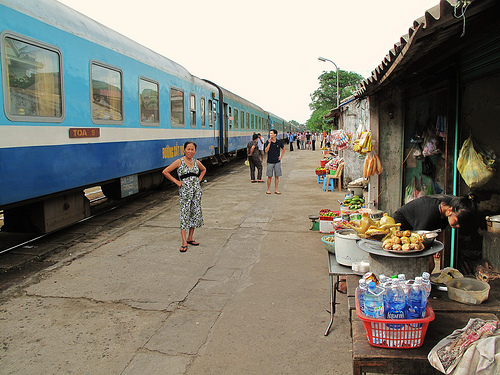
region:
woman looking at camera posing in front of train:
[166, 133, 222, 263]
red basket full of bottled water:
[344, 258, 436, 365]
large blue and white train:
[7, 35, 244, 185]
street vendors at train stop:
[322, 53, 438, 371]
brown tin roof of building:
[345, 0, 490, 112]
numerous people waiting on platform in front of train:
[174, 98, 329, 260]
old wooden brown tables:
[340, 296, 497, 367]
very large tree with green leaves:
[304, 56, 369, 138]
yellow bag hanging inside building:
[445, 118, 499, 194]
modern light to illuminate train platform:
[315, 40, 348, 120]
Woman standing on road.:
[156, 120, 273, 260]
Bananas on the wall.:
[357, 125, 465, 212]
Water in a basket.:
[339, 283, 456, 370]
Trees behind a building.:
[245, 24, 498, 241]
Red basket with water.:
[340, 266, 450, 356]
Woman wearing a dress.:
[147, 142, 239, 314]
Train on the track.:
[104, 17, 402, 276]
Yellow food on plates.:
[342, 196, 449, 293]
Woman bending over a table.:
[397, 167, 497, 253]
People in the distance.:
[232, 97, 330, 204]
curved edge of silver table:
[318, 281, 353, 341]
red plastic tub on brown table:
[337, 278, 442, 362]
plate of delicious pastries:
[368, 220, 435, 271]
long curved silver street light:
[307, 45, 344, 124]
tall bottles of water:
[343, 263, 432, 332]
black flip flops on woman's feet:
[175, 230, 230, 264]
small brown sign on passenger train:
[63, 121, 119, 143]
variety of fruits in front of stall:
[329, 182, 369, 206]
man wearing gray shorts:
[260, 159, 297, 183]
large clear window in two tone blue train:
[70, 47, 147, 134]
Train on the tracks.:
[7, 12, 346, 282]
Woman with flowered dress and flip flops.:
[160, 122, 207, 264]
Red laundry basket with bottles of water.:
[334, 272, 441, 365]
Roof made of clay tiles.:
[341, 0, 486, 114]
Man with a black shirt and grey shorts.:
[258, 111, 297, 211]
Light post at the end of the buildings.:
[308, 34, 353, 127]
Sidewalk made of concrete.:
[8, 95, 351, 374]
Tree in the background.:
[286, 40, 371, 144]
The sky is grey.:
[17, 1, 457, 157]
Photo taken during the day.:
[13, 0, 495, 366]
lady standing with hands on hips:
[161, 101, 243, 297]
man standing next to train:
[255, 123, 303, 211]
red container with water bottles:
[346, 256, 464, 373]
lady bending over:
[358, 176, 498, 286]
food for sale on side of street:
[311, 179, 446, 367]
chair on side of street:
[317, 154, 354, 204]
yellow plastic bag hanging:
[457, 130, 498, 212]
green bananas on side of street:
[335, 178, 382, 221]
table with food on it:
[319, 225, 419, 337]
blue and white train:
[0, 0, 324, 218]